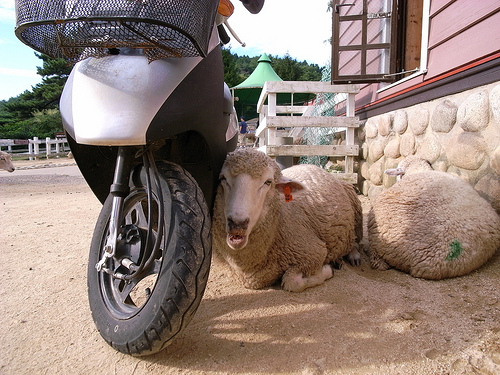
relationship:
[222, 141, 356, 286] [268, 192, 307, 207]
lamb has tag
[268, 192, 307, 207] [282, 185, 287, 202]
tag has numbers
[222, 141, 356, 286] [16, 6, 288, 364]
lamb near motorcycle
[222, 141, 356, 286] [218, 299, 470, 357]
lamb on ground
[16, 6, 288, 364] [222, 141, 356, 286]
motorcycle near lamb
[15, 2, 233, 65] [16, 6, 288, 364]
basket on motorcycle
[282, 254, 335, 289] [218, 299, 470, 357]
leg on ground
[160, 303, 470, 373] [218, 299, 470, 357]
shadow on ground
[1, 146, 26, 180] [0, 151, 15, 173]
sheep has head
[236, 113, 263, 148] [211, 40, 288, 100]
people under umbrella